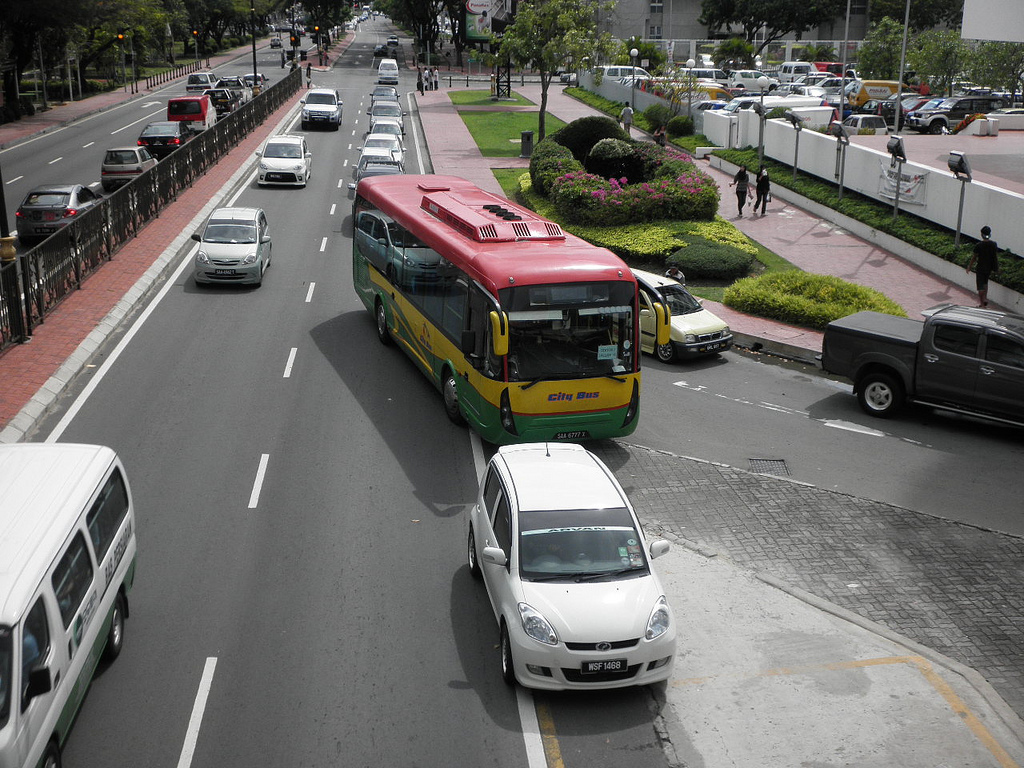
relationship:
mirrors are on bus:
[482, 309, 519, 357] [348, 163, 647, 436]